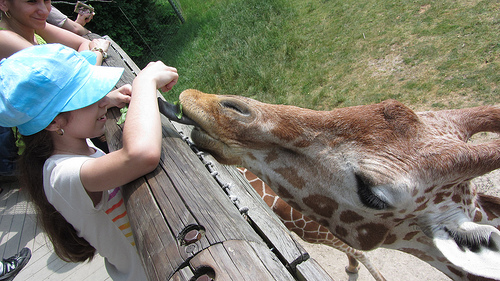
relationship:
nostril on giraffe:
[220, 97, 250, 115] [182, 78, 488, 276]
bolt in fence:
[192, 265, 214, 280] [77, 32, 334, 278]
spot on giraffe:
[263, 150, 280, 164] [182, 78, 488, 276]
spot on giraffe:
[300, 186, 340, 221] [182, 78, 488, 276]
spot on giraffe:
[431, 189, 448, 204] [152, 89, 498, 276]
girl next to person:
[4, 34, 188, 279] [2, 0, 115, 65]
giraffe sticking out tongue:
[173, 82, 495, 258] [158, 94, 184, 123]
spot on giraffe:
[452, 192, 465, 203] [152, 89, 498, 276]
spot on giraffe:
[273, 166, 307, 190] [152, 89, 498, 276]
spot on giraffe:
[300, 193, 340, 219] [152, 89, 498, 276]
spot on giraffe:
[414, 194, 427, 204] [152, 89, 498, 276]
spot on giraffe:
[337, 208, 361, 225] [152, 89, 498, 276]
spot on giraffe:
[262, 146, 277, 163] [152, 89, 498, 276]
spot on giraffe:
[275, 182, 292, 197] [152, 89, 498, 276]